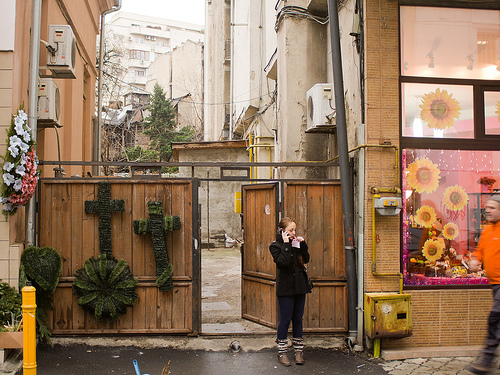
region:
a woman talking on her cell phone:
[237, 201, 326, 373]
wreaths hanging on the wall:
[34, 189, 175, 337]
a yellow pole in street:
[19, 286, 71, 370]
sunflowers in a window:
[409, 160, 471, 294]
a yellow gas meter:
[359, 284, 422, 374]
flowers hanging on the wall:
[0, 131, 52, 219]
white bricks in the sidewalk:
[397, 357, 468, 372]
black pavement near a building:
[149, 348, 254, 372]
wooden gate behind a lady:
[232, 186, 271, 323]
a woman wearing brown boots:
[255, 204, 350, 374]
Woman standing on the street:
[262, 210, 323, 372]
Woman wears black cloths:
[260, 217, 331, 374]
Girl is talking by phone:
[260, 211, 332, 368]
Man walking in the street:
[461, 195, 496, 372]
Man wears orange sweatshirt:
[451, 187, 498, 374]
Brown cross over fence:
[125, 195, 190, 307]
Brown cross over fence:
[72, 175, 132, 263]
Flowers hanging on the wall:
[5, 107, 43, 227]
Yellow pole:
[14, 281, 51, 373]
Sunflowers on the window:
[398, 84, 478, 286]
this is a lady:
[255, 209, 312, 374]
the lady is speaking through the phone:
[270, 216, 292, 241]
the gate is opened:
[197, 182, 272, 334]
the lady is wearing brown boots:
[272, 333, 302, 360]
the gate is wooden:
[245, 188, 277, 317]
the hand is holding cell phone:
[279, 230, 285, 236]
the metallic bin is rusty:
[362, 296, 412, 341]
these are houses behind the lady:
[5, 8, 356, 117]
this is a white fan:
[305, 83, 334, 125]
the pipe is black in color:
[335, 76, 360, 336]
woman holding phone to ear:
[258, 214, 320, 311]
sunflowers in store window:
[398, 152, 468, 269]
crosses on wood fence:
[72, 178, 190, 308]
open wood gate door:
[225, 173, 285, 332]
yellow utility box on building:
[356, 269, 419, 347]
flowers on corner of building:
[5, 96, 47, 218]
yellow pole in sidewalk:
[11, 273, 49, 373]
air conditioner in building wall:
[296, 68, 343, 140]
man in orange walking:
[465, 186, 497, 364]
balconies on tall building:
[127, 16, 186, 93]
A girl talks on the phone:
[262, 213, 325, 367]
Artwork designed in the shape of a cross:
[129, 196, 189, 296]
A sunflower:
[413, 85, 468, 136]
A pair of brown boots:
[273, 336, 314, 367]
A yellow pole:
[16, 280, 41, 372]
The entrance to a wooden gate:
[187, 174, 287, 336]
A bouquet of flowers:
[1, 105, 39, 215]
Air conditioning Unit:
[303, 80, 344, 134]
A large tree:
[135, 80, 202, 175]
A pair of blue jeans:
[273, 290, 315, 340]